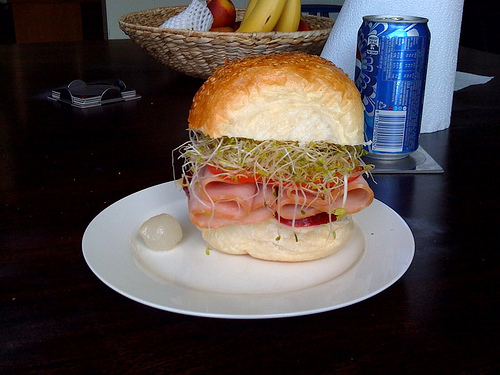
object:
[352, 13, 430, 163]
cola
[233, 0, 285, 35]
banana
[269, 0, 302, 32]
banana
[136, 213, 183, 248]
pearl onion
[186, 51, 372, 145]
bun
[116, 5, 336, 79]
basket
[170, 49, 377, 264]
sandwhich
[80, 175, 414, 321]
plate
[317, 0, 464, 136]
towels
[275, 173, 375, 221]
meat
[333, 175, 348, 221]
sprouts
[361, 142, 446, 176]
coaster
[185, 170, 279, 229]
meat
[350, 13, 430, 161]
can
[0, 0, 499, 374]
table